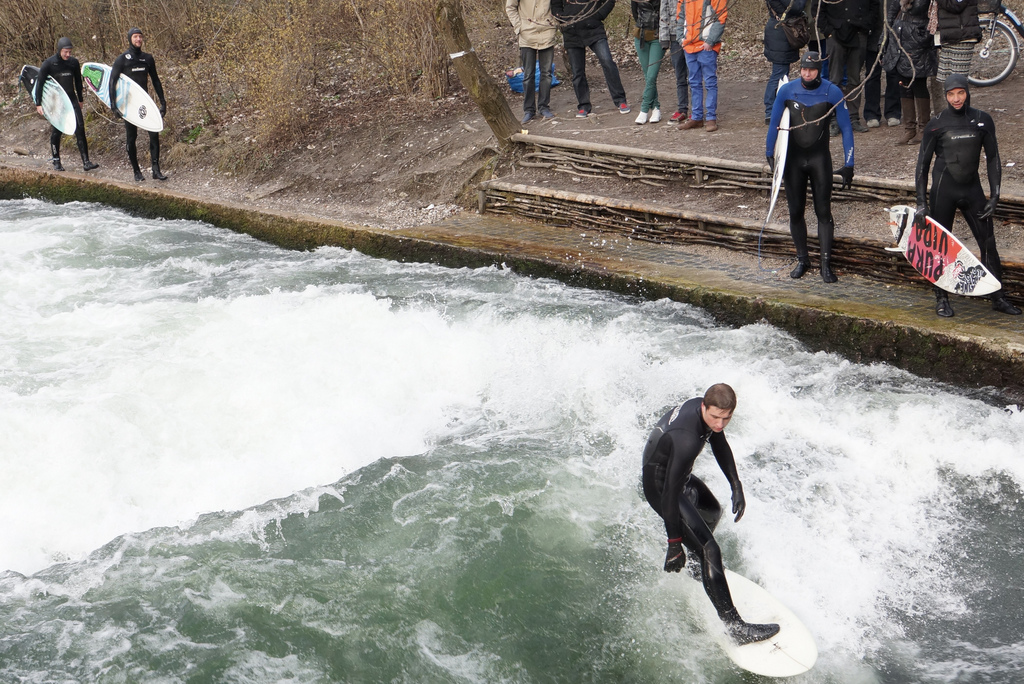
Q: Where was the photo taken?
A: Water.